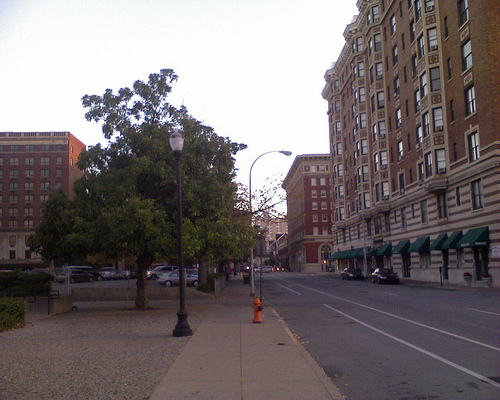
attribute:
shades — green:
[329, 224, 487, 267]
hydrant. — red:
[250, 297, 267, 327]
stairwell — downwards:
[30, 289, 55, 316]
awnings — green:
[390, 230, 498, 254]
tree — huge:
[26, 70, 252, 310]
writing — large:
[0, 130, 72, 139]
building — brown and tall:
[0, 132, 89, 283]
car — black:
[371, 268, 396, 281]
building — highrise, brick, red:
[4, 130, 86, 285]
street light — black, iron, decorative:
[165, 120, 190, 340]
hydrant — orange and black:
[249, 294, 267, 324]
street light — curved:
[247, 147, 299, 296]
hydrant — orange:
[249, 295, 268, 327]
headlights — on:
[275, 267, 284, 269]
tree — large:
[57, 80, 267, 308]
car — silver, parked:
[154, 261, 199, 286]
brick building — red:
[1, 129, 86, 283]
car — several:
[158, 270, 199, 287]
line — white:
[297, 291, 454, 398]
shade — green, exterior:
[459, 219, 498, 250]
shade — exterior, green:
[438, 227, 465, 252]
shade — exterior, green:
[426, 230, 448, 253]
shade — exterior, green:
[372, 237, 391, 259]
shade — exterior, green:
[348, 242, 367, 262]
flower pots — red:
[459, 269, 491, 287]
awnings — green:
[416, 225, 486, 259]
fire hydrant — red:
[250, 297, 265, 324]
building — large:
[321, 0, 498, 291]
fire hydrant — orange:
[252, 297, 263, 324]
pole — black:
[168, 151, 190, 336]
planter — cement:
[453, 269, 485, 289]